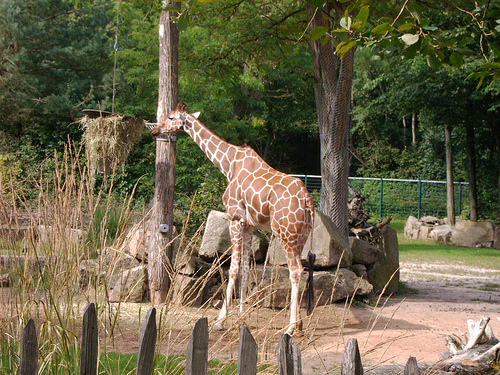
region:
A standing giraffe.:
[148, 102, 317, 339]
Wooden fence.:
[13, 303, 420, 372]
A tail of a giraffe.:
[298, 181, 319, 316]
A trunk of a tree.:
[315, 110, 351, 232]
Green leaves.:
[326, 10, 429, 61]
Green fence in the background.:
[296, 173, 469, 229]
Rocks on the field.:
[197, 204, 381, 309]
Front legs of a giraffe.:
[215, 229, 252, 330]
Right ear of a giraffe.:
[190, 107, 201, 122]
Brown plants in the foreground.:
[3, 138, 141, 373]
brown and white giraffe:
[155, 104, 316, 331]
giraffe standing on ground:
[153, 102, 315, 336]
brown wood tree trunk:
[151, 2, 175, 302]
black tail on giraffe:
[306, 253, 315, 310]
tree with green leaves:
[244, 3, 478, 258]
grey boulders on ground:
[103, 211, 396, 298]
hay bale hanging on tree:
[79, 115, 140, 171]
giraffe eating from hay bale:
[153, 104, 315, 334]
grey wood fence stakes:
[3, 303, 423, 373]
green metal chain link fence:
[291, 173, 475, 223]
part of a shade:
[386, 310, 404, 329]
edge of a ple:
[250, 341, 270, 362]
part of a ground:
[395, 318, 417, 354]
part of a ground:
[402, 300, 417, 325]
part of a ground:
[363, 305, 381, 324]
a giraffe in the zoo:
[109, 80, 368, 345]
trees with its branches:
[233, 19, 458, 137]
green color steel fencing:
[378, 178, 471, 214]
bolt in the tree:
[156, 223, 173, 234]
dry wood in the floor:
[448, 322, 498, 372]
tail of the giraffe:
[306, 245, 319, 316]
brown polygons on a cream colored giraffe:
[200, 133, 315, 268]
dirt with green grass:
[421, 243, 488, 303]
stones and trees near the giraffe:
[127, 205, 381, 296]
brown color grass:
[37, 183, 126, 324]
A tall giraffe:
[152, 104, 342, 334]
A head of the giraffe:
[150, 102, 201, 145]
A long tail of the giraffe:
[301, 181, 318, 323]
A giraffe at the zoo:
[146, 98, 342, 342]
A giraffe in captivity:
[149, 95, 444, 340]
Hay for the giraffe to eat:
[74, 98, 147, 175]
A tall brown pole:
[147, 1, 185, 305]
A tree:
[293, 4, 378, 254]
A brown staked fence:
[14, 300, 425, 374]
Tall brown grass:
[1, 161, 128, 347]